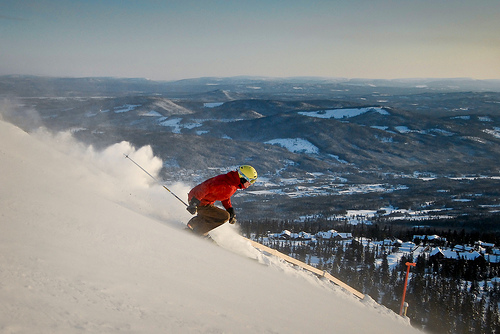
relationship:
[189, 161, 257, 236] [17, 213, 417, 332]
man skiing on slope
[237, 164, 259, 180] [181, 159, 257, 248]
helmet on man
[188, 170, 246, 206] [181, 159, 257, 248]
coat on man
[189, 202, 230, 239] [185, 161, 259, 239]
pants on man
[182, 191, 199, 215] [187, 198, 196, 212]
glove on hand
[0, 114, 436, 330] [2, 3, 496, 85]
snow in air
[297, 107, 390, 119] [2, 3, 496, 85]
snow in air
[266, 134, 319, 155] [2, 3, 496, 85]
snow in air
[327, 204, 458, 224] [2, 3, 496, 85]
snow in air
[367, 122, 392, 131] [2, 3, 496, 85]
snow in air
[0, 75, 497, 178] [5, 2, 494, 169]
hills in background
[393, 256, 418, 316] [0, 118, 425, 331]
pole in ground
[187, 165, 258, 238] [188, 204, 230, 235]
man has pants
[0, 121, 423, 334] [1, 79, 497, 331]
snow on ground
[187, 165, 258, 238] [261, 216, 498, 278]
man above buildings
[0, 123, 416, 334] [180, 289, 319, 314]
mountain have snow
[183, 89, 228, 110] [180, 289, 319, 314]
mountain have snow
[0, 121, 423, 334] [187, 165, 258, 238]
snow billowing behind man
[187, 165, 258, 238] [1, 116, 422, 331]
man going down hill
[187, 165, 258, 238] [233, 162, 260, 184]
man wearing helmet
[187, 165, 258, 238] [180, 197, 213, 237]
man has pants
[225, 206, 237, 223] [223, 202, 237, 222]
glove on hand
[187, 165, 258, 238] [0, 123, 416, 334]
man skiing down mountain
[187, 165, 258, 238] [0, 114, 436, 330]
man skiing in snow